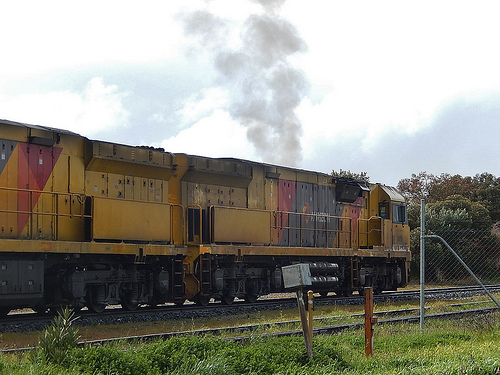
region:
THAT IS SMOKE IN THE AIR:
[261, 49, 313, 127]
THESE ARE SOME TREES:
[424, 172, 498, 264]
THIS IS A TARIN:
[11, 141, 81, 245]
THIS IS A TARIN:
[88, 139, 182, 249]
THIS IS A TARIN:
[212, 176, 262, 244]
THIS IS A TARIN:
[288, 198, 339, 248]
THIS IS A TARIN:
[355, 188, 406, 278]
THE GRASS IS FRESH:
[147, 341, 208, 369]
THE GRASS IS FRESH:
[240, 336, 257, 366]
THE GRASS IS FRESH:
[118, 335, 152, 369]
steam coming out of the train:
[203, 27, 307, 150]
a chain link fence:
[423, 226, 495, 326]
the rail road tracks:
[18, 268, 497, 330]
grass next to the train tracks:
[71, 326, 393, 372]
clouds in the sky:
[49, 73, 194, 128]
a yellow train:
[4, 110, 411, 299]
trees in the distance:
[406, 162, 494, 279]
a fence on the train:
[268, 206, 360, 248]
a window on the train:
[391, 205, 408, 222]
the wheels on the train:
[72, 270, 269, 307]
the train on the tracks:
[0, 105, 430, 279]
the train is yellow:
[16, 129, 410, 241]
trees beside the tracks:
[405, 168, 498, 245]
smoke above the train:
[214, 23, 334, 153]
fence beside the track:
[405, 195, 499, 338]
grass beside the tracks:
[55, 340, 318, 374]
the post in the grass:
[360, 283, 388, 358]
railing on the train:
[262, 199, 379, 235]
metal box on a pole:
[277, 258, 324, 287]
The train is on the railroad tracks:
[5, 88, 496, 363]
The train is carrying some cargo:
[1, 103, 497, 364]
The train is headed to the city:
[3, 100, 495, 358]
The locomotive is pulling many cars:
[16, 82, 487, 358]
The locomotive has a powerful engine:
[20, 115, 493, 351]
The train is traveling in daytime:
[0, 37, 487, 362]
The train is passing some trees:
[2, 77, 488, 372]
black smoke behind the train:
[211, 30, 317, 175]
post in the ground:
[354, 284, 379, 359]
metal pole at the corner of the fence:
[416, 188, 432, 330]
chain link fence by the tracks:
[420, 235, 497, 362]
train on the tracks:
[20, 123, 422, 305]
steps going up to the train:
[198, 240, 218, 301]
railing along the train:
[268, 204, 385, 240]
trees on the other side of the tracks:
[416, 178, 483, 282]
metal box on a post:
[279, 262, 310, 308]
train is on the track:
[1, 115, 413, 315]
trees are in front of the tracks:
[325, 170, 498, 280]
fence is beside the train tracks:
[416, 197, 498, 342]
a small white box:
[282, 260, 312, 291]